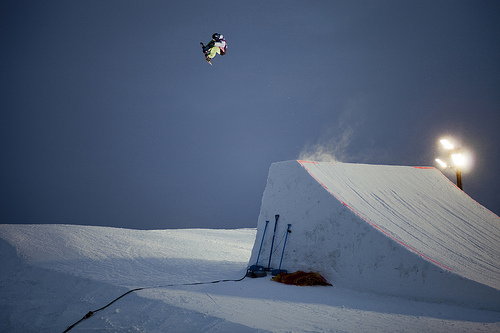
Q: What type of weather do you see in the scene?
A: It is clear.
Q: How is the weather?
A: It is clear.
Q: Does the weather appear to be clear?
A: Yes, it is clear.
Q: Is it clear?
A: Yes, it is clear.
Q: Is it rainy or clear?
A: It is clear.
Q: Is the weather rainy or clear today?
A: It is clear.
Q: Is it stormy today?
A: No, it is clear.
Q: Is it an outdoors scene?
A: Yes, it is outdoors.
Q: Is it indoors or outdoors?
A: It is outdoors.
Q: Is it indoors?
A: No, it is outdoors.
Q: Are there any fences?
A: No, there are no fences.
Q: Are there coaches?
A: No, there are no coaches.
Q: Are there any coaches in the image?
A: No, there are no coaches.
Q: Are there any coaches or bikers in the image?
A: No, there are no coaches or bikers.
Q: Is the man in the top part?
A: Yes, the man is in the top of the image.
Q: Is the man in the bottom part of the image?
A: No, the man is in the top of the image.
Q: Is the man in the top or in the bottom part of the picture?
A: The man is in the top of the image.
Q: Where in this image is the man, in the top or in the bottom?
A: The man is in the top of the image.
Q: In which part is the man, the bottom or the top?
A: The man is in the top of the image.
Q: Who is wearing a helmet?
A: The man is wearing a helmet.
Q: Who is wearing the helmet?
A: The man is wearing a helmet.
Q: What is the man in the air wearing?
A: The man is wearing a helmet.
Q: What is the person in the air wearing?
A: The man is wearing a helmet.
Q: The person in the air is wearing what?
A: The man is wearing a helmet.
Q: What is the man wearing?
A: The man is wearing a helmet.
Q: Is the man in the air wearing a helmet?
A: Yes, the man is wearing a helmet.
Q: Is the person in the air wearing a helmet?
A: Yes, the man is wearing a helmet.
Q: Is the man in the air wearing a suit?
A: No, the man is wearing a helmet.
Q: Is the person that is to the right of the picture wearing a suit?
A: No, the man is wearing a helmet.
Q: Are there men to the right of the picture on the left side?
A: Yes, there is a man to the right of the picture.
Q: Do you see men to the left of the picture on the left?
A: No, the man is to the right of the picture.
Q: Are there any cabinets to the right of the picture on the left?
A: No, there is a man to the right of the picture.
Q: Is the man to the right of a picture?
A: Yes, the man is to the right of a picture.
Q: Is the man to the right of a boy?
A: No, the man is to the right of a picture.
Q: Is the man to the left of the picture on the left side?
A: No, the man is to the right of the picture.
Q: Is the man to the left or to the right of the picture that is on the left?
A: The man is to the right of the picture.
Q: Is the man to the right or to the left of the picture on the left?
A: The man is to the right of the picture.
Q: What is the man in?
A: The man is in the air.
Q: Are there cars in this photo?
A: No, there are no cars.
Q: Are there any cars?
A: No, there are no cars.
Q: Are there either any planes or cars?
A: No, there are no cars or planes.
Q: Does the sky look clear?
A: Yes, the sky is clear.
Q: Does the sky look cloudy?
A: No, the sky is clear.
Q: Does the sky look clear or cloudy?
A: The sky is clear.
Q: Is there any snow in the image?
A: Yes, there is snow.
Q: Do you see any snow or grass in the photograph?
A: Yes, there is snow.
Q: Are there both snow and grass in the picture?
A: No, there is snow but no grass.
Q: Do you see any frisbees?
A: No, there are no frisbees.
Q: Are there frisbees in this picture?
A: No, there are no frisbees.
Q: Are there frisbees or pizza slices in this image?
A: No, there are no frisbees or pizza slices.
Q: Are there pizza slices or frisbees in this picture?
A: No, there are no frisbees or pizza slices.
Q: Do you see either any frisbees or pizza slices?
A: No, there are no frisbees or pizza slices.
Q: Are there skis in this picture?
A: Yes, there are skis.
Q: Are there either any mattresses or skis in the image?
A: Yes, there are skis.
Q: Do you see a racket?
A: No, there are no rackets.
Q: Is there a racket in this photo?
A: No, there are no rackets.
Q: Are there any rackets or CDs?
A: No, there are no rackets or cds.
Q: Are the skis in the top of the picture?
A: Yes, the skis are in the top of the image.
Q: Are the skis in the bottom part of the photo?
A: No, the skis are in the top of the image.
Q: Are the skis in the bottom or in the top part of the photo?
A: The skis are in the top of the image.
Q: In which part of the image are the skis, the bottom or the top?
A: The skis are in the top of the image.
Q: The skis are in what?
A: The skis are in the air.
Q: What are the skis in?
A: The skis are in the air.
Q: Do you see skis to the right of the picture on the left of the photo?
A: Yes, there are skis to the right of the picture.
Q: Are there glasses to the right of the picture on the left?
A: No, there are skis to the right of the picture.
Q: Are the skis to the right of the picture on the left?
A: Yes, the skis are to the right of the picture.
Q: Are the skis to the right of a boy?
A: No, the skis are to the right of the picture.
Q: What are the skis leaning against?
A: The skis are leaning against the hill.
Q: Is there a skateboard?
A: No, there are no skateboards.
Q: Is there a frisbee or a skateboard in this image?
A: No, there are no skateboards or frisbees.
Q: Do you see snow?
A: Yes, there is snow.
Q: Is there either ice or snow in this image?
A: Yes, there is snow.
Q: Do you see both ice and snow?
A: No, there is snow but no ice.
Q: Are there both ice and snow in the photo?
A: No, there is snow but no ice.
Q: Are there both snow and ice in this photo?
A: No, there is snow but no ice.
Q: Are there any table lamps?
A: No, there are no table lamps.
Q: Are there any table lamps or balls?
A: No, there are no table lamps or balls.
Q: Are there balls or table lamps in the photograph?
A: No, there are no table lamps or balls.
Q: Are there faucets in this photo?
A: No, there are no faucets.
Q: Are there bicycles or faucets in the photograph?
A: No, there are no faucets or bicycles.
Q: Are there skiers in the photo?
A: No, there are no skiers.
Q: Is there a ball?
A: No, there are no balls.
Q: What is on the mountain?
A: The picture is on the mountain.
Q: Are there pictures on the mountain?
A: Yes, there is a picture on the mountain.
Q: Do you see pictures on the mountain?
A: Yes, there is a picture on the mountain.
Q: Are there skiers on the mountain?
A: No, there is a picture on the mountain.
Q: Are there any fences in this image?
A: No, there are no fences.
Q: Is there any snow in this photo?
A: Yes, there is snow.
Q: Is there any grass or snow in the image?
A: Yes, there is snow.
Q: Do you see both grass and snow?
A: No, there is snow but no grass.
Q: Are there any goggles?
A: No, there are no goggles.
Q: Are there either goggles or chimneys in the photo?
A: No, there are no goggles or chimneys.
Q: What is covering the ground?
A: The snow is covering the ground.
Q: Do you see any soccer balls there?
A: No, there are no soccer balls.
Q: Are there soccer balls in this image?
A: No, there are no soccer balls.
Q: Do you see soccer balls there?
A: No, there are no soccer balls.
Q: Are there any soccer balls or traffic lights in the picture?
A: No, there are no soccer balls or traffic lights.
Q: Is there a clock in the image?
A: No, there are no clocks.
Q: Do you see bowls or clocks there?
A: No, there are no clocks or bowls.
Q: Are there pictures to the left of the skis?
A: Yes, there is a picture to the left of the skis.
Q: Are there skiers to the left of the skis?
A: No, there is a picture to the left of the skis.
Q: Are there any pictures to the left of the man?
A: Yes, there is a picture to the left of the man.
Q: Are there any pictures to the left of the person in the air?
A: Yes, there is a picture to the left of the man.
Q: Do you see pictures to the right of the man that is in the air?
A: No, the picture is to the left of the man.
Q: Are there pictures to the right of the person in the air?
A: No, the picture is to the left of the man.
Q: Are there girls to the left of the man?
A: No, there is a picture to the left of the man.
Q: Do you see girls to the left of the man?
A: No, there is a picture to the left of the man.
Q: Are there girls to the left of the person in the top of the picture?
A: No, there is a picture to the left of the man.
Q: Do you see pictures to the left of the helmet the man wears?
A: Yes, there is a picture to the left of the helmet.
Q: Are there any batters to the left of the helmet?
A: No, there is a picture to the left of the helmet.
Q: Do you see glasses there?
A: No, there are no glasses.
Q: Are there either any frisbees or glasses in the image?
A: No, there are no glasses or frisbees.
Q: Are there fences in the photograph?
A: No, there are no fences.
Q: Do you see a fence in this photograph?
A: No, there are no fences.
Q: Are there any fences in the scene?
A: No, there are no fences.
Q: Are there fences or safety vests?
A: No, there are no fences or safety vests.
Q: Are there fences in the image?
A: No, there are no fences.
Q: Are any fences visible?
A: No, there are no fences.